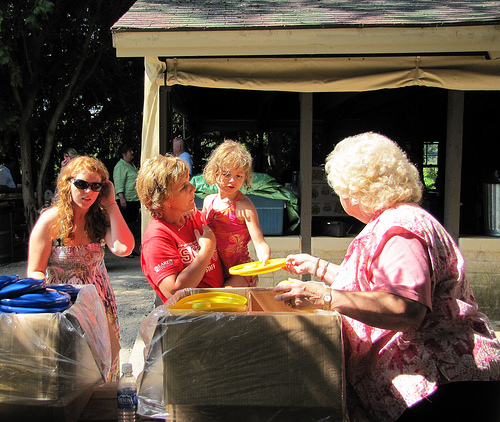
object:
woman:
[272, 130, 499, 420]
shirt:
[332, 203, 499, 420]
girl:
[26, 156, 136, 383]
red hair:
[37, 147, 111, 245]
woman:
[135, 152, 218, 305]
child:
[201, 138, 272, 288]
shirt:
[140, 213, 228, 305]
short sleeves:
[143, 237, 184, 287]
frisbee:
[228, 258, 290, 276]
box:
[154, 286, 348, 421]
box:
[1, 283, 111, 421]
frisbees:
[0, 274, 82, 314]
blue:
[0, 275, 71, 313]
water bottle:
[115, 363, 138, 421]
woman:
[114, 141, 140, 258]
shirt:
[111, 158, 143, 202]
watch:
[323, 287, 333, 312]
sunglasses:
[73, 178, 104, 192]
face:
[71, 171, 102, 209]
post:
[443, 90, 464, 247]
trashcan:
[485, 176, 498, 239]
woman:
[61, 147, 81, 169]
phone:
[61, 156, 70, 167]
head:
[324, 131, 424, 224]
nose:
[229, 177, 237, 184]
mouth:
[189, 196, 195, 203]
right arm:
[315, 256, 349, 285]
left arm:
[331, 208, 438, 339]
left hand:
[273, 276, 332, 310]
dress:
[45, 240, 122, 381]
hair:
[135, 152, 190, 220]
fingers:
[282, 257, 300, 274]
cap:
[122, 363, 133, 374]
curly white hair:
[320, 131, 423, 217]